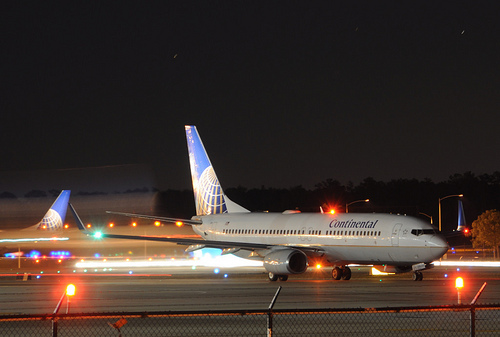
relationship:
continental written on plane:
[328, 217, 380, 229] [68, 123, 452, 282]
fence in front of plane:
[1, 302, 499, 337] [68, 123, 452, 282]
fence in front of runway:
[1, 302, 499, 337] [1, 266, 499, 335]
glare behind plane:
[76, 250, 270, 272] [68, 123, 452, 282]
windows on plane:
[221, 227, 383, 238] [68, 123, 452, 282]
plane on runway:
[68, 123, 452, 282] [1, 266, 499, 335]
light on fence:
[63, 281, 78, 314] [1, 302, 499, 337]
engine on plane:
[263, 247, 310, 276] [68, 123, 452, 282]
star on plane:
[401, 228, 409, 236] [68, 123, 452, 282]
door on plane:
[390, 221, 403, 248] [68, 123, 452, 282]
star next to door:
[401, 228, 409, 236] [390, 221, 403, 248]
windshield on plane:
[410, 226, 440, 237] [68, 123, 452, 282]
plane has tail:
[68, 123, 452, 282] [183, 123, 243, 214]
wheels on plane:
[330, 266, 352, 280] [68, 123, 452, 282]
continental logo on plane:
[328, 217, 380, 229] [68, 123, 452, 282]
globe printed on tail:
[196, 164, 228, 215] [183, 123, 243, 214]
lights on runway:
[6, 249, 76, 265] [1, 266, 499, 335]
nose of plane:
[407, 219, 451, 267] [68, 123, 452, 282]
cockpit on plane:
[402, 215, 437, 242] [68, 123, 452, 282]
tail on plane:
[183, 123, 243, 214] [68, 123, 452, 282]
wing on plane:
[67, 201, 324, 253] [68, 123, 452, 282]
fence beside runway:
[1, 302, 499, 337] [1, 266, 499, 335]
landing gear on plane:
[408, 265, 426, 283] [68, 123, 452, 282]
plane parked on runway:
[68, 123, 452, 282] [1, 266, 499, 335]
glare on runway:
[76, 250, 270, 272] [1, 266, 499, 335]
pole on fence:
[267, 283, 284, 310] [1, 302, 499, 337]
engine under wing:
[263, 247, 310, 276] [67, 201, 324, 253]